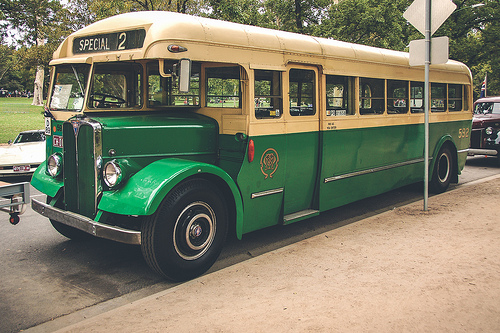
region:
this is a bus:
[20, 5, 496, 283]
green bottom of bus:
[11, 75, 486, 256]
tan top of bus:
[42, 8, 495, 169]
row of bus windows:
[180, 55, 476, 120]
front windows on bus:
[30, 38, 180, 138]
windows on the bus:
[223, 48, 418, 140]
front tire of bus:
[134, 160, 259, 290]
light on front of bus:
[87, 136, 131, 201]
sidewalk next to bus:
[303, 234, 413, 301]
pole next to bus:
[380, 24, 463, 205]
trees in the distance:
[248, 3, 394, 34]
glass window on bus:
[48, 61, 85, 111]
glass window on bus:
[83, 62, 147, 107]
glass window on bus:
[149, 63, 201, 107]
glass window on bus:
[203, 65, 240, 106]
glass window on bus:
[251, 68, 282, 117]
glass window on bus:
[288, 65, 315, 115]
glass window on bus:
[326, 74, 351, 115]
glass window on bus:
[358, 77, 385, 114]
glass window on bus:
[386, 78, 408, 113]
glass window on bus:
[408, 79, 425, 113]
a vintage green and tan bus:
[31, 9, 474, 281]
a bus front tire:
[140, 178, 227, 281]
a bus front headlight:
[102, 160, 116, 186]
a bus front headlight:
[45, 156, 62, 178]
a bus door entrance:
[282, 62, 319, 216]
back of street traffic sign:
[401, 1, 456, 36]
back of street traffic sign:
[407, 39, 447, 66]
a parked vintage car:
[467, 98, 498, 158]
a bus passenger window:
[252, 68, 280, 118]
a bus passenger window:
[326, 74, 356, 117]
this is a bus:
[27, 23, 451, 295]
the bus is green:
[85, 33, 423, 213]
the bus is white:
[160, 45, 398, 156]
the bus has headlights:
[37, 140, 177, 234]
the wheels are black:
[148, 194, 225, 279]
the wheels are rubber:
[144, 221, 201, 285]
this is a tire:
[125, 200, 217, 258]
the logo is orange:
[234, 137, 319, 191]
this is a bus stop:
[317, 227, 491, 322]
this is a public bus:
[64, 27, 361, 214]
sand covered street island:
[18, 173, 498, 332]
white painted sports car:
[0, 129, 49, 183]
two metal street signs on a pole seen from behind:
[401, 0, 456, 212]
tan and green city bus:
[27, 10, 474, 282]